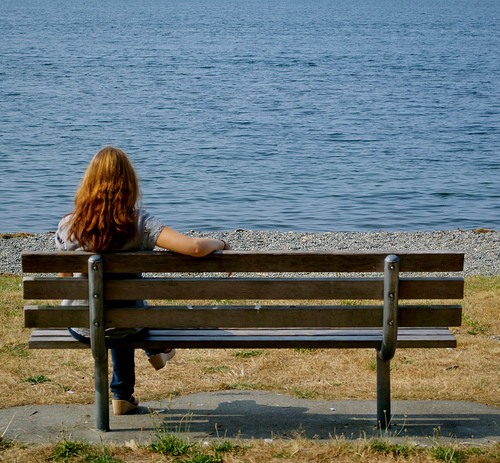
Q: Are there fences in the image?
A: No, there are no fences.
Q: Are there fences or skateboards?
A: No, there are no fences or skateboards.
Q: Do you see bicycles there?
A: No, there are no bicycles.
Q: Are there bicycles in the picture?
A: No, there are no bicycles.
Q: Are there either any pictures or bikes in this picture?
A: No, there are no bikes or pictures.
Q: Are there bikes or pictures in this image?
A: No, there are no bikes or pictures.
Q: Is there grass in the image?
A: Yes, there is grass.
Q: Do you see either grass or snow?
A: Yes, there is grass.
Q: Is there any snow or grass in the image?
A: Yes, there is grass.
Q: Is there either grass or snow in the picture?
A: Yes, there is grass.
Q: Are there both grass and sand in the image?
A: No, there is grass but no sand.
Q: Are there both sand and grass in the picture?
A: No, there is grass but no sand.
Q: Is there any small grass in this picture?
A: Yes, there is small grass.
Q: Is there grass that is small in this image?
A: Yes, there is small grass.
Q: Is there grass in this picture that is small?
A: Yes, there is grass that is small.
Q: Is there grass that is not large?
A: Yes, there is small grass.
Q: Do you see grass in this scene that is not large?
A: Yes, there is small grass.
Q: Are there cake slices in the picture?
A: No, there are no cake slices.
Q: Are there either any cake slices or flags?
A: No, there are no cake slices or flags.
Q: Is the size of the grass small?
A: Yes, the grass is small.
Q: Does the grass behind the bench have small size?
A: Yes, the grass is small.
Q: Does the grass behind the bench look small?
A: Yes, the grass is small.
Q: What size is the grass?
A: The grass is small.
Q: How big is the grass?
A: The grass is small.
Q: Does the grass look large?
A: No, the grass is small.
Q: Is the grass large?
A: No, the grass is small.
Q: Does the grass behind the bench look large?
A: No, the grass is small.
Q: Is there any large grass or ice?
A: No, there is grass but it is small.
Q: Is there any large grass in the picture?
A: No, there is grass but it is small.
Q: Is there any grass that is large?
A: No, there is grass but it is small.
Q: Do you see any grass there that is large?
A: No, there is grass but it is small.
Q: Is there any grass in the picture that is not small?
A: No, there is grass but it is small.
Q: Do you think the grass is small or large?
A: The grass is small.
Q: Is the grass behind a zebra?
A: No, the grass is behind a bench.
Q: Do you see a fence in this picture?
A: No, there are no fences.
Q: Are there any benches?
A: Yes, there is a bench.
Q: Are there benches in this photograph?
A: Yes, there is a bench.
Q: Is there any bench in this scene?
A: Yes, there is a bench.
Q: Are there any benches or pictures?
A: Yes, there is a bench.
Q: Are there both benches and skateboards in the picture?
A: No, there is a bench but no skateboards.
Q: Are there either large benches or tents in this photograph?
A: Yes, there is a large bench.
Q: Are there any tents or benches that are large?
A: Yes, the bench is large.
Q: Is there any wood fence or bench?
A: Yes, there is a wood bench.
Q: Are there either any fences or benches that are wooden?
A: Yes, the bench is wooden.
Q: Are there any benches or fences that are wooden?
A: Yes, the bench is wooden.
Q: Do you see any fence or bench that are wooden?
A: Yes, the bench is wooden.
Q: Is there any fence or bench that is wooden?
A: Yes, the bench is wooden.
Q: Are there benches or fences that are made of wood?
A: Yes, the bench is made of wood.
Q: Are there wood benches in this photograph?
A: Yes, there is a wood bench.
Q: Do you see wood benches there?
A: Yes, there is a wood bench.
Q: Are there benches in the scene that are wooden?
A: Yes, there is a bench that is wooden.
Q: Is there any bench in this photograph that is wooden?
A: Yes, there is a bench that is wooden.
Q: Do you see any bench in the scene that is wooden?
A: Yes, there is a bench that is wooden.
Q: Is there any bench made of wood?
A: Yes, there is a bench that is made of wood.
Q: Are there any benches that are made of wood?
A: Yes, there is a bench that is made of wood.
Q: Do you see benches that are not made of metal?
A: Yes, there is a bench that is made of wood.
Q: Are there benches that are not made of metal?
A: Yes, there is a bench that is made of wood.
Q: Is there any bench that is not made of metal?
A: Yes, there is a bench that is made of wood.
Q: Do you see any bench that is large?
A: Yes, there is a large bench.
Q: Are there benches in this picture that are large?
A: Yes, there is a bench that is large.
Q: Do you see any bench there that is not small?
A: Yes, there is a large bench.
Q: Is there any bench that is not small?
A: Yes, there is a large bench.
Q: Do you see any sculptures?
A: No, there are no sculptures.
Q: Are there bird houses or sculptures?
A: No, there are no sculptures or bird houses.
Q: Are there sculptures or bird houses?
A: No, there are no sculptures or bird houses.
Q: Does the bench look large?
A: Yes, the bench is large.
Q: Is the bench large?
A: Yes, the bench is large.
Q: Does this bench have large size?
A: Yes, the bench is large.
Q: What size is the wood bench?
A: The bench is large.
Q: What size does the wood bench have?
A: The bench has large size.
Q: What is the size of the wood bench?
A: The bench is large.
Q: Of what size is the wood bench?
A: The bench is large.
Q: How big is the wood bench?
A: The bench is large.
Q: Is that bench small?
A: No, the bench is large.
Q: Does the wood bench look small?
A: No, the bench is large.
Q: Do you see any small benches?
A: No, there is a bench but it is large.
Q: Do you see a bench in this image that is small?
A: No, there is a bench but it is large.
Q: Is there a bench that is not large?
A: No, there is a bench but it is large.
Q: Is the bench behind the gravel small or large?
A: The bench is large.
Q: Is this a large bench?
A: Yes, this is a large bench.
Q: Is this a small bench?
A: No, this is a large bench.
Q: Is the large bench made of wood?
A: Yes, the bench is made of wood.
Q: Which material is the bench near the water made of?
A: The bench is made of wood.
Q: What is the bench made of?
A: The bench is made of wood.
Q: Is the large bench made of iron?
A: No, the bench is made of wood.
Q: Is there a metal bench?
A: No, there is a bench but it is made of wood.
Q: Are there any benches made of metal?
A: No, there is a bench but it is made of wood.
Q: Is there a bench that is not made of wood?
A: No, there is a bench but it is made of wood.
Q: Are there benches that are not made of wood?
A: No, there is a bench but it is made of wood.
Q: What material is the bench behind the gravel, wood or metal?
A: The bench is made of wood.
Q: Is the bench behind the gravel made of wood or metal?
A: The bench is made of wood.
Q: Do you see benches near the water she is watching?
A: Yes, there is a bench near the water.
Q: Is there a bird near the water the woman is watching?
A: No, there is a bench near the water.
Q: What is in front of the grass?
A: The bench is in front of the grass.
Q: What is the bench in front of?
A: The bench is in front of the grass.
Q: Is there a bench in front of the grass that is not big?
A: Yes, there is a bench in front of the grass.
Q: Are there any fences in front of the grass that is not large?
A: No, there is a bench in front of the grass.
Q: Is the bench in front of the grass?
A: Yes, the bench is in front of the grass.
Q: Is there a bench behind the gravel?
A: Yes, there is a bench behind the gravel.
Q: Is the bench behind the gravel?
A: Yes, the bench is behind the gravel.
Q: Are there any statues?
A: No, there are no statues.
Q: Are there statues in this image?
A: No, there are no statues.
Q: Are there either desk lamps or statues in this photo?
A: No, there are no statues or desk lamps.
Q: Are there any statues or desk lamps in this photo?
A: No, there are no statues or desk lamps.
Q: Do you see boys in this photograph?
A: No, there are no boys.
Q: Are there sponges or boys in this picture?
A: No, there are no boys or sponges.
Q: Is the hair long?
A: Yes, the hair is long.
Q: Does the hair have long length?
A: Yes, the hair is long.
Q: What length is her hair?
A: The hair is long.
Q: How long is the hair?
A: The hair is long.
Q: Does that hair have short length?
A: No, the hair is long.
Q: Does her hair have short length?
A: No, the hair is long.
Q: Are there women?
A: Yes, there is a woman.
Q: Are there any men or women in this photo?
A: Yes, there is a woman.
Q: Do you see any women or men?
A: Yes, there is a woman.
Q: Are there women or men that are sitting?
A: Yes, the woman is sitting.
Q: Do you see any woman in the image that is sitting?
A: Yes, there is a woman that is sitting.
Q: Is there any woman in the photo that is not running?
A: Yes, there is a woman that is sitting.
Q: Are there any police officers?
A: No, there are no police officers.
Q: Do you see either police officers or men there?
A: No, there are no police officers or men.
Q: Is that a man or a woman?
A: That is a woman.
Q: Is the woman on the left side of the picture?
A: Yes, the woman is on the left of the image.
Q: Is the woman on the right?
A: No, the woman is on the left of the image.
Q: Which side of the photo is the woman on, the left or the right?
A: The woman is on the left of the image.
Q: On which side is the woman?
A: The woman is on the left of the image.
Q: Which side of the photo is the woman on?
A: The woman is on the left of the image.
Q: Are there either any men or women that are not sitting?
A: No, there is a woman but she is sitting.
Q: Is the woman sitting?
A: Yes, the woman is sitting.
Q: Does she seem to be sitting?
A: Yes, the woman is sitting.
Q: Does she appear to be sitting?
A: Yes, the woman is sitting.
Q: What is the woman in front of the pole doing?
A: The woman is sitting.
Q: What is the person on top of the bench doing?
A: The woman is sitting.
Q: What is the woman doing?
A: The woman is sitting.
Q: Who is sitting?
A: The woman is sitting.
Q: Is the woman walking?
A: No, the woman is sitting.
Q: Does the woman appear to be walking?
A: No, the woman is sitting.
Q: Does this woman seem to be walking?
A: No, the woman is sitting.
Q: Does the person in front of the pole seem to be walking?
A: No, the woman is sitting.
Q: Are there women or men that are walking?
A: No, there is a woman but she is sitting.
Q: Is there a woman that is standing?
A: No, there is a woman but she is sitting.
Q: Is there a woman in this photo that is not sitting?
A: No, there is a woman but she is sitting.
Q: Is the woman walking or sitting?
A: The woman is sitting.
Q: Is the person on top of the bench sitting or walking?
A: The woman is sitting.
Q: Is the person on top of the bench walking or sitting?
A: The woman is sitting.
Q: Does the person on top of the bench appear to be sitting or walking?
A: The woman is sitting.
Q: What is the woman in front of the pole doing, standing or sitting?
A: The woman is sitting.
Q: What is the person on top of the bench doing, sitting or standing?
A: The woman is sitting.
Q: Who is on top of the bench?
A: The woman is on top of the bench.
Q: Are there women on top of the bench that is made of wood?
A: Yes, there is a woman on top of the bench.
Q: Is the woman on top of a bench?
A: Yes, the woman is on top of a bench.